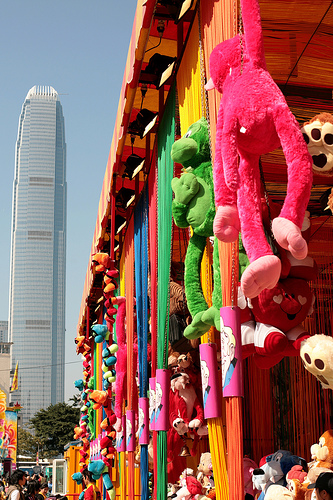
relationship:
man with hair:
[6, 470, 27, 499] [9, 469, 27, 484]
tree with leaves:
[28, 401, 82, 458] [26, 401, 81, 456]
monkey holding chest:
[169, 117, 252, 340] [181, 171, 213, 226]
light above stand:
[127, 107, 160, 141] [167, 430, 332, 499]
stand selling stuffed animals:
[167, 430, 332, 499] [168, 427, 332, 499]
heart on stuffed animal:
[297, 294, 308, 306] [238, 276, 319, 369]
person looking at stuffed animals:
[308, 469, 333, 499] [168, 427, 332, 499]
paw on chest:
[170, 171, 200, 205] [181, 171, 213, 226]